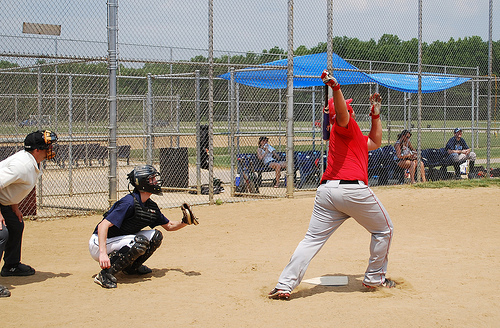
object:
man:
[267, 67, 398, 305]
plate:
[297, 274, 351, 286]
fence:
[0, 0, 498, 218]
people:
[254, 136, 298, 189]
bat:
[320, 70, 331, 140]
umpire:
[0, 128, 62, 299]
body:
[265, 69, 397, 300]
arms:
[330, 89, 383, 150]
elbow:
[162, 223, 178, 231]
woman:
[392, 127, 425, 184]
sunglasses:
[402, 132, 412, 138]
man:
[443, 127, 479, 180]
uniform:
[446, 137, 478, 180]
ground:
[1, 175, 499, 327]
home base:
[301, 275, 353, 286]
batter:
[268, 69, 396, 300]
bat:
[240, 163, 255, 193]